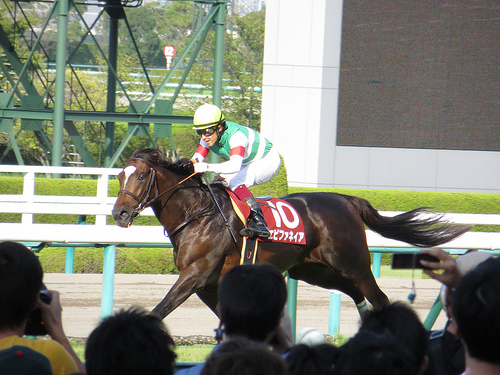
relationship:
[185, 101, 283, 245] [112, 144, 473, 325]
jockey on horse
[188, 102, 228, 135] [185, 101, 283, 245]
helmet on jockey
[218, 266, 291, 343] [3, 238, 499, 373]
spectator in crowd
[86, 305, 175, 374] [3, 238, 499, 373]
person in crowd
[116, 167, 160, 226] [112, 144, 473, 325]
bridal on horse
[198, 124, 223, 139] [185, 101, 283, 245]
goggles on jockey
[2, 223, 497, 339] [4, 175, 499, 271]
fence by grass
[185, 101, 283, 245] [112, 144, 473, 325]
jockey riding horse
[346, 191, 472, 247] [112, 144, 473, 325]
tail on horse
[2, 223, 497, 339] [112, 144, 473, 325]
fence by horse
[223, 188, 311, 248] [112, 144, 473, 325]
blanket on horse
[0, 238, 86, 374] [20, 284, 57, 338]
man holding camera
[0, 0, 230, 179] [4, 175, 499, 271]
tower by grass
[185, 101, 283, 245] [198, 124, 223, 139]
jockey wearing goggles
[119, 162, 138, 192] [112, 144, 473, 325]
spot on horse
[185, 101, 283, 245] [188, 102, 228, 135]
jockey with a helmet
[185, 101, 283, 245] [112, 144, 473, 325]
jockey on h horse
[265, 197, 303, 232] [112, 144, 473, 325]
number on horse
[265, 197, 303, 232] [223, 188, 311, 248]
number on blanket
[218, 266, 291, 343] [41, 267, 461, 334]
spectator at track